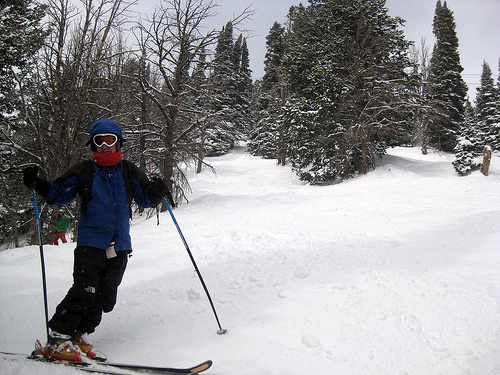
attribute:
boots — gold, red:
[49, 324, 98, 366]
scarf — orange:
[90, 148, 124, 165]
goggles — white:
[91, 130, 120, 148]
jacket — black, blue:
[26, 159, 187, 251]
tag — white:
[98, 240, 130, 266]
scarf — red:
[90, 152, 125, 165]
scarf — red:
[51, 146, 122, 251]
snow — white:
[428, 207, 451, 257]